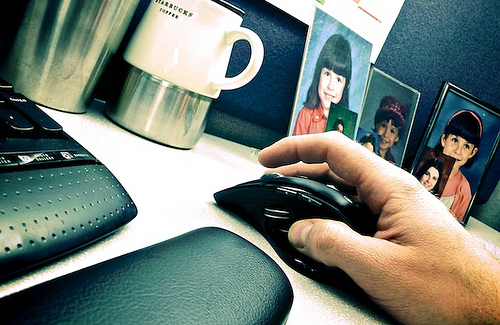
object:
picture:
[409, 81, 499, 229]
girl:
[292, 33, 352, 140]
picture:
[287, 5, 375, 142]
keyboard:
[0, 77, 138, 283]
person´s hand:
[255, 129, 499, 324]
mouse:
[212, 169, 379, 293]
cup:
[102, 66, 215, 150]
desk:
[2, 79, 496, 322]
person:
[253, 130, 497, 324]